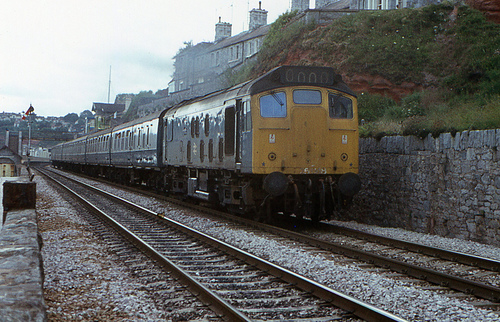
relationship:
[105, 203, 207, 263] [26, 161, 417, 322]
train tracks are on train tracks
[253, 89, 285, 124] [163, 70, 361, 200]
windshield of train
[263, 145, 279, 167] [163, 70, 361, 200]
headlight on train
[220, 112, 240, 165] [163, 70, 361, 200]
door on train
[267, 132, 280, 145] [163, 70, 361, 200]
number on train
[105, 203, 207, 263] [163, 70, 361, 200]
train tracks are near train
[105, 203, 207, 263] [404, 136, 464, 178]
train tracks near stone wall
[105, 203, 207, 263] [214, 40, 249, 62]
train tracks near building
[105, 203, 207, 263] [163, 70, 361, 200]
train tracks are next to train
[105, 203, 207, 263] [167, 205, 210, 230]
train tracks next to rocks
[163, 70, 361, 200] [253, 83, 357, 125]
train has windows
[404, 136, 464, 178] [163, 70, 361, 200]
stone wall next to train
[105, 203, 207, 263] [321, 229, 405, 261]
train tracks next to train tracks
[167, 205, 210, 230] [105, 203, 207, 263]
rocks on right side of train tracks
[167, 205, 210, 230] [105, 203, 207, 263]
rocks near train tracks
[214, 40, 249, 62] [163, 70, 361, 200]
building near train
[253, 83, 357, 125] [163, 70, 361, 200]
windows in front of train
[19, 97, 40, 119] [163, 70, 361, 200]
flags flying near train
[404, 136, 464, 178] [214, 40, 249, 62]
stone wall near building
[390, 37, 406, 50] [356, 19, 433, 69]
small flowers next to hill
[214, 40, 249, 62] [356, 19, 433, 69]
building next to hill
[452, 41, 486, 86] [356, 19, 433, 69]
grass on hill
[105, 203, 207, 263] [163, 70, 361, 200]
train tracks near train